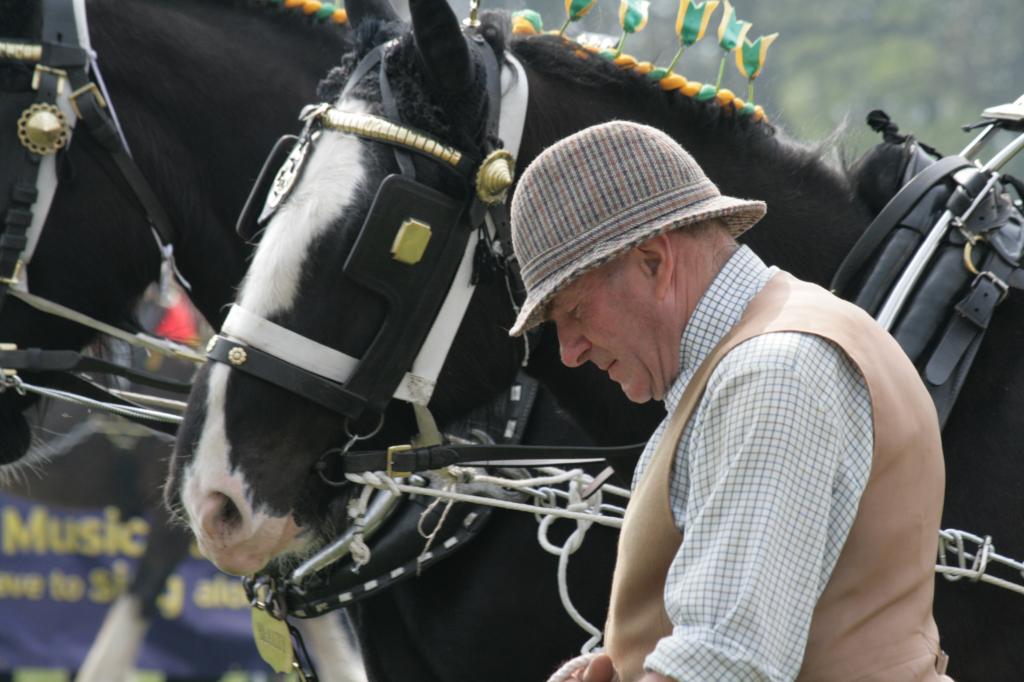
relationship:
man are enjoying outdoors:
[547, 217, 955, 682] [123, 103, 966, 624]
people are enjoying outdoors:
[20, 479, 528, 682] [24, 203, 867, 682]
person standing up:
[519, 116, 941, 549] [579, 306, 904, 682]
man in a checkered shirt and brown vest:
[493, 315, 991, 682] [855, 390, 944, 650]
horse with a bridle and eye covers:
[276, 103, 428, 259] [307, 203, 444, 474]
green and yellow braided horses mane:
[828, 209, 857, 227] [575, 107, 736, 136]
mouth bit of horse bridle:
[253, 392, 435, 663] [249, 274, 509, 679]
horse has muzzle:
[162, 15, 1014, 674] [154, 466, 306, 573]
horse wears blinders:
[162, 0, 869, 674] [330, 164, 497, 301]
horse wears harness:
[158, 15, 876, 674] [169, 15, 545, 435]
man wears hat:
[482, 90, 966, 678] [478, 93, 787, 335]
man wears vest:
[482, 90, 966, 678] [594, 268, 970, 677]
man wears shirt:
[482, 90, 966, 678] [650, 227, 888, 677]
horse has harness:
[162, 0, 869, 674] [210, 26, 552, 446]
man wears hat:
[482, 90, 966, 678] [478, 101, 779, 350]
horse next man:
[162, 0, 869, 674] [482, 90, 966, 678]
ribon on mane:
[519, 15, 764, 115] [516, 15, 787, 163]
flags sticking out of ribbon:
[553, 0, 776, 98] [522, 17, 780, 145]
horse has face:
[162, 15, 1014, 674] [164, 35, 441, 580]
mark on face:
[192, 82, 376, 450] [164, 35, 441, 580]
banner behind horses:
[1, 397, 276, 676] [1, 0, 1023, 673]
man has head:
[507, 119, 951, 680] [537, 205, 745, 407]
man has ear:
[482, 90, 966, 678] [628, 227, 680, 292]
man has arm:
[482, 90, 966, 678] [632, 332, 857, 680]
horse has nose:
[162, 15, 1014, 674] [166, 469, 287, 562]